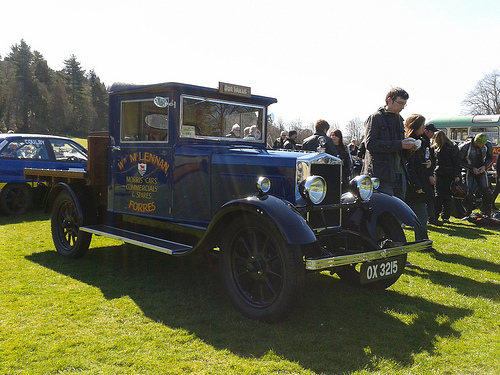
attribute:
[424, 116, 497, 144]
bus — light blue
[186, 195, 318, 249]
fender — shiny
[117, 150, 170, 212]
text — yellow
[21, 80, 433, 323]
car — antique, black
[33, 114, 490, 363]
grass — green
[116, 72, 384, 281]
truck — antique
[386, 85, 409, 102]
hair — black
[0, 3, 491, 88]
sky — daytime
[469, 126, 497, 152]
hat — green